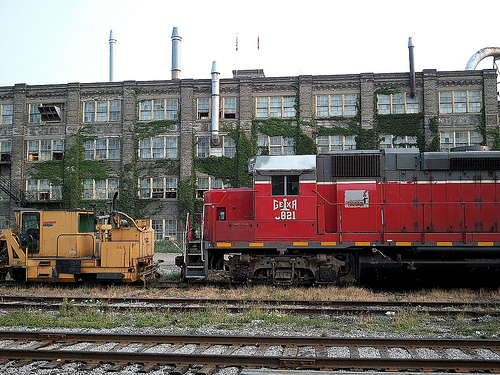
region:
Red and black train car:
[180, 146, 497, 291]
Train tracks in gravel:
[86, 325, 371, 370]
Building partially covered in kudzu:
[15, 76, 200, 201]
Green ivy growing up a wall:
[115, 110, 191, 210]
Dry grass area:
[227, 286, 367, 296]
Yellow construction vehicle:
[0, 205, 160, 285]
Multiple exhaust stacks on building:
[105, 25, 230, 117]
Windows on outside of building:
[70, 90, 185, 161]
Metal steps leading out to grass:
[177, 202, 212, 299]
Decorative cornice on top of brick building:
[0, 70, 490, 99]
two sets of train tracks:
[142, 292, 321, 370]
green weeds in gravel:
[230, 310, 345, 335]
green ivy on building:
[202, 123, 265, 185]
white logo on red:
[262, 192, 303, 234]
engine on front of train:
[202, 142, 317, 269]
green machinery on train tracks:
[17, 198, 160, 292]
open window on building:
[215, 92, 240, 127]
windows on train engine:
[265, 170, 302, 205]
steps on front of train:
[180, 227, 210, 284]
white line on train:
[391, 169, 466, 196]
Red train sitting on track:
[135, 147, 480, 276]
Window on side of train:
[267, 166, 302, 195]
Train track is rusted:
[136, 329, 471, 369]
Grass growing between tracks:
[169, 299, 311, 328]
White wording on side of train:
[265, 187, 303, 237]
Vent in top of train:
[316, 146, 391, 178]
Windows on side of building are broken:
[27, 132, 70, 165]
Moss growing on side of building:
[210, 87, 279, 204]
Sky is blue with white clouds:
[21, 0, 96, 61]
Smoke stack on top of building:
[392, 9, 439, 116]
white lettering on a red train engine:
[269, 198, 306, 223]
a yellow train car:
[12, 202, 162, 297]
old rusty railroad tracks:
[117, 329, 209, 362]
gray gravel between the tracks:
[329, 345, 348, 358]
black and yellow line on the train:
[280, 238, 495, 250]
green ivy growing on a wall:
[58, 150, 77, 194]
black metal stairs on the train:
[180, 230, 217, 278]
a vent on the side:
[327, 152, 387, 176]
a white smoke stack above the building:
[160, 21, 187, 75]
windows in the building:
[64, 80, 498, 155]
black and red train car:
[206, 152, 498, 293]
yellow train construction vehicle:
[4, 208, 157, 288]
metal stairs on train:
[186, 211, 206, 278]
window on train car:
[273, 174, 299, 199]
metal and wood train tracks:
[1, 329, 497, 373]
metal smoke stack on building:
[211, 64, 220, 154]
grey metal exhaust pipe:
[466, 43, 498, 70]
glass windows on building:
[138, 177, 178, 198]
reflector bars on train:
[213, 241, 498, 250]